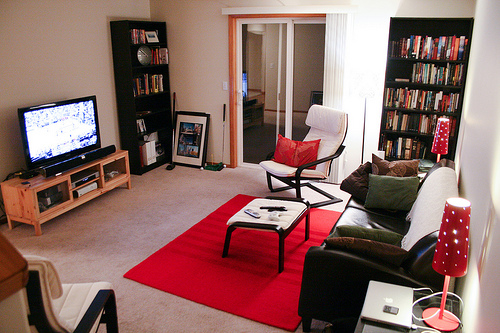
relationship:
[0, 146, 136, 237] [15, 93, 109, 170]
stand holds tv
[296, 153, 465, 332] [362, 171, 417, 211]
couch has pillow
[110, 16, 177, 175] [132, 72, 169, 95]
bookshelf holds books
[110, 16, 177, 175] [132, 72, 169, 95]
bookshelf has books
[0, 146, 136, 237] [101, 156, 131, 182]
stand has opening